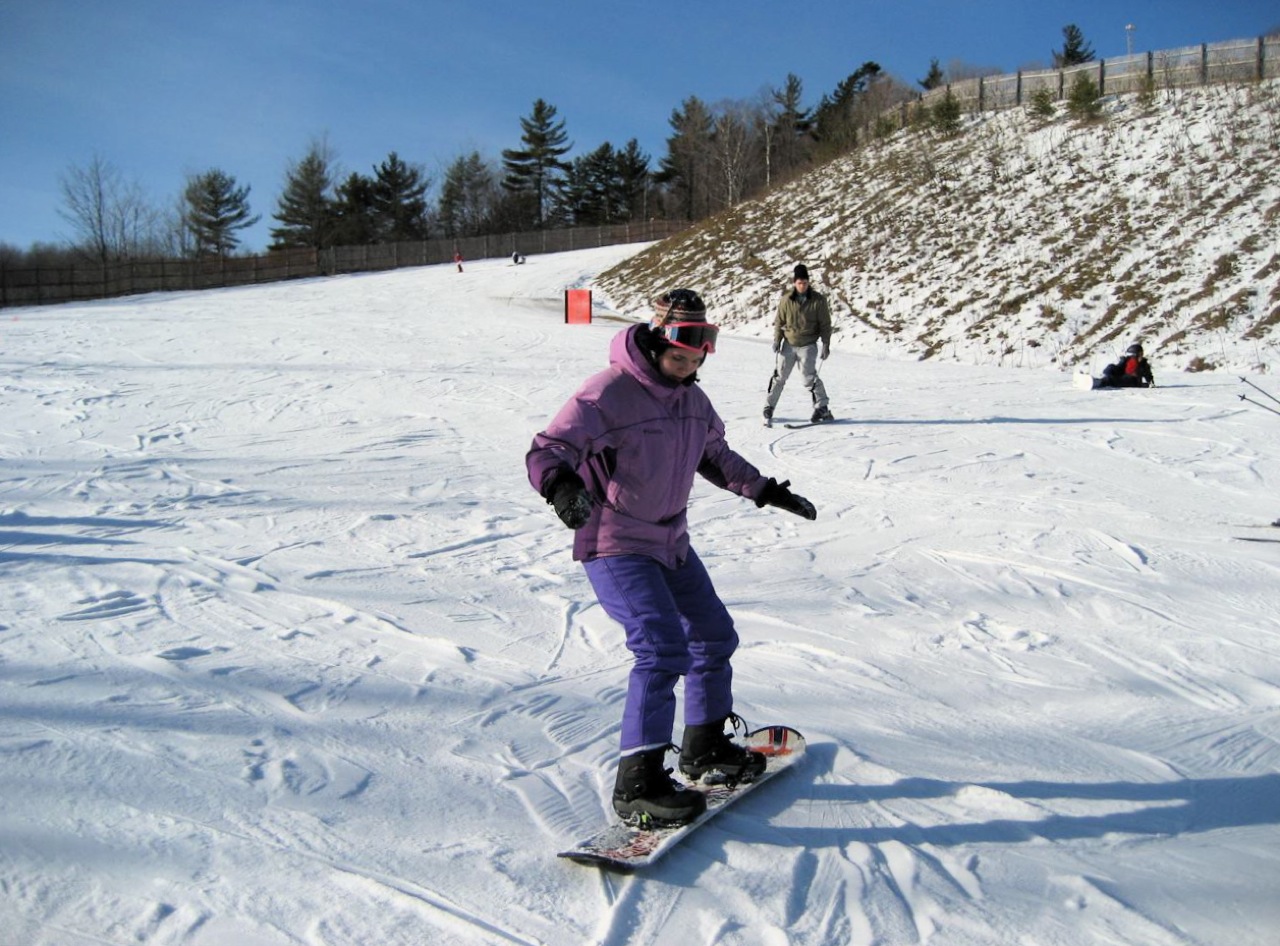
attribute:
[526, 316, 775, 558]
jacket — purple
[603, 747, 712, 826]
shoe — black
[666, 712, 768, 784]
shoe — black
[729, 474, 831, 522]
glove — black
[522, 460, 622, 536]
glove — black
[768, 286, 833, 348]
jacket — green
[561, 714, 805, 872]
snowboard — white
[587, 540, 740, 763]
pants — purple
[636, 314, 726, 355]
goggles — pink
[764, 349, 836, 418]
pants — tan 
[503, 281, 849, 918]
boarder — snow 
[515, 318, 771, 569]
coat — pink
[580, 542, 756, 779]
pants —  purple ski 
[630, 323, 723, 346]
ski goggles — pink